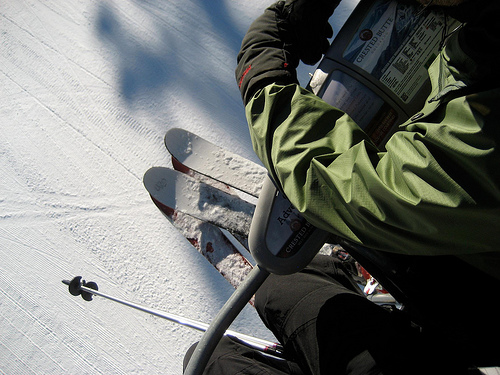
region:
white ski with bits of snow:
[168, 136, 255, 233]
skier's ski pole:
[76, 255, 203, 336]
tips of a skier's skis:
[108, 127, 231, 227]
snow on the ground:
[24, 175, 104, 254]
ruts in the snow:
[85, 127, 126, 177]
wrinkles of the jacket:
[292, 161, 432, 223]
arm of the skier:
[244, 132, 452, 276]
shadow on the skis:
[165, 188, 240, 308]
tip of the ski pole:
[56, 270, 73, 305]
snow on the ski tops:
[171, 154, 246, 275]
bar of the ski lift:
[178, 215, 278, 374]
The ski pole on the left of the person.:
[66, 269, 292, 369]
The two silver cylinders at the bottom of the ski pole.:
[75, 273, 107, 302]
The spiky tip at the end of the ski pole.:
[58, 271, 68, 286]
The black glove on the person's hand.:
[232, 1, 331, 111]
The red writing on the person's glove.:
[228, 55, 260, 86]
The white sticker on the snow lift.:
[350, 22, 445, 97]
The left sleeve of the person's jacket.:
[255, 65, 495, 235]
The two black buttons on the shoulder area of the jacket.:
[400, 76, 460, 122]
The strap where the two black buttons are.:
[400, 75, 450, 135]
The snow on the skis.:
[172, 144, 273, 275]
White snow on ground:
[3, 1, 197, 373]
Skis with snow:
[137, 118, 309, 318]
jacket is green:
[244, 13, 497, 288]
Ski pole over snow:
[57, 253, 321, 354]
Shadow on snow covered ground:
[84, 6, 341, 196]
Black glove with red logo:
[227, 1, 336, 102]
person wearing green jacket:
[229, 0, 494, 272]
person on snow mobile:
[212, 11, 497, 365]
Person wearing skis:
[148, 23, 497, 370]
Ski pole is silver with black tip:
[54, 266, 319, 367]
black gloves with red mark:
[224, 13, 312, 94]